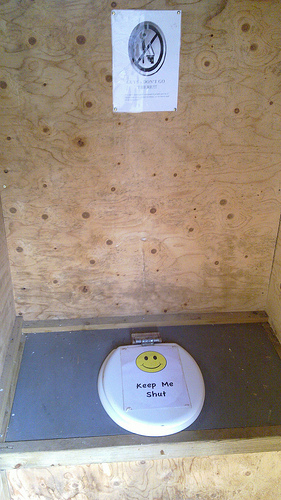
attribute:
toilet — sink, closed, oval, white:
[100, 330, 203, 454]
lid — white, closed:
[103, 341, 203, 435]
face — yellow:
[139, 349, 164, 375]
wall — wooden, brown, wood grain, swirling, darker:
[75, 150, 244, 290]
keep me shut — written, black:
[134, 378, 179, 405]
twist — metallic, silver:
[129, 331, 165, 349]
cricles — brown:
[64, 30, 113, 126]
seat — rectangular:
[5, 324, 279, 446]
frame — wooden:
[0, 306, 281, 452]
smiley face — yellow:
[134, 349, 169, 379]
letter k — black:
[130, 378, 144, 391]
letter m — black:
[158, 376, 172, 392]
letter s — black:
[144, 389, 156, 399]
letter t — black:
[159, 387, 169, 401]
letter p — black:
[146, 380, 156, 394]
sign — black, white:
[115, 13, 178, 113]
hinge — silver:
[126, 324, 167, 345]